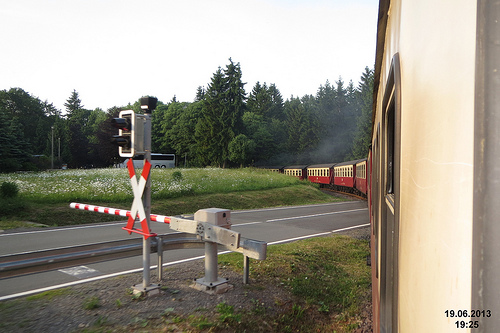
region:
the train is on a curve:
[318, 174, 370, 203]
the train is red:
[336, 176, 348, 187]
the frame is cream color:
[311, 167, 325, 177]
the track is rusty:
[342, 189, 358, 199]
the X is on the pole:
[120, 155, 156, 237]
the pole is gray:
[138, 248, 155, 273]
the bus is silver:
[160, 161, 172, 169]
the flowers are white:
[73, 179, 89, 191]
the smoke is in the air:
[306, 125, 345, 155]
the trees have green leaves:
[200, 110, 225, 134]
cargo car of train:
[350, 149, 380, 201]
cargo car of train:
[331, 153, 353, 190]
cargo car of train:
[302, 156, 327, 194]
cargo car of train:
[284, 151, 305, 179]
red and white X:
[125, 147, 165, 242]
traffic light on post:
[102, 95, 166, 170]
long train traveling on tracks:
[278, 132, 382, 227]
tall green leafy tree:
[61, 83, 98, 151]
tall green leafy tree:
[241, 55, 288, 153]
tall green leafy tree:
[181, 56, 251, 156]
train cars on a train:
[267, 141, 384, 213]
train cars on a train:
[284, 149, 405, 191]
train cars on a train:
[281, 161, 366, 222]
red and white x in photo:
[114, 147, 183, 242]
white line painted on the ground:
[35, 281, 102, 296]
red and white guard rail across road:
[61, 193, 232, 255]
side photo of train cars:
[305, 149, 387, 199]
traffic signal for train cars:
[94, 99, 161, 171]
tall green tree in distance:
[201, 69, 256, 151]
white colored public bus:
[111, 150, 206, 182]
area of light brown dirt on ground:
[75, 295, 155, 321]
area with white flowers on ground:
[43, 183, 104, 200]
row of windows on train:
[329, 165, 355, 181]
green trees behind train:
[359, 81, 369, 151]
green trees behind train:
[319, 98, 330, 120]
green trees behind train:
[299, 104, 301, 135]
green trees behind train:
[291, 105, 294, 122]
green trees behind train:
[271, 107, 273, 133]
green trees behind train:
[234, 94, 239, 138]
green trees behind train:
[194, 96, 214, 129]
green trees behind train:
[165, 117, 178, 142]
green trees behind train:
[80, 118, 94, 124]